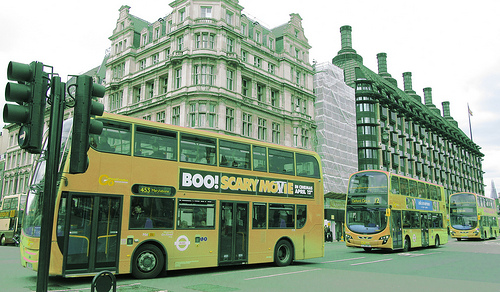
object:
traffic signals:
[3, 104, 29, 124]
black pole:
[37, 76, 67, 292]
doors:
[64, 195, 121, 274]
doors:
[391, 210, 403, 248]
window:
[181, 133, 217, 165]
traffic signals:
[6, 82, 32, 103]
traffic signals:
[94, 83, 106, 98]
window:
[253, 203, 267, 229]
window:
[269, 203, 295, 229]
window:
[297, 205, 307, 229]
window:
[176, 199, 214, 228]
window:
[131, 196, 174, 228]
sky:
[382, 1, 500, 49]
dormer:
[200, 7, 212, 18]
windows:
[253, 146, 267, 172]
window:
[219, 140, 250, 169]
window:
[134, 131, 177, 161]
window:
[89, 124, 132, 155]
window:
[296, 153, 321, 179]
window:
[391, 176, 399, 194]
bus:
[344, 170, 449, 253]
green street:
[232, 237, 499, 290]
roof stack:
[332, 25, 364, 64]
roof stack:
[376, 52, 398, 88]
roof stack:
[402, 72, 422, 104]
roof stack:
[423, 87, 443, 116]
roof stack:
[441, 101, 459, 127]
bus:
[21, 111, 326, 278]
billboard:
[179, 168, 316, 199]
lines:
[245, 268, 321, 281]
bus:
[448, 192, 499, 241]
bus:
[0, 193, 27, 246]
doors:
[221, 202, 248, 266]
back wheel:
[275, 239, 294, 266]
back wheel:
[435, 235, 439, 248]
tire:
[363, 247, 372, 252]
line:
[350, 258, 393, 265]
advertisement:
[182, 172, 314, 197]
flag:
[467, 105, 473, 117]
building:
[333, 45, 486, 214]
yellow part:
[103, 159, 143, 175]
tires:
[401, 239, 410, 252]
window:
[226, 107, 234, 132]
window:
[257, 85, 262, 106]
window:
[271, 91, 275, 110]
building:
[0, 0, 357, 243]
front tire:
[132, 244, 165, 279]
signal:
[7, 61, 32, 82]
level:
[29, 112, 325, 205]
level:
[20, 190, 325, 278]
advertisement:
[415, 198, 433, 211]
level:
[104, 57, 315, 122]